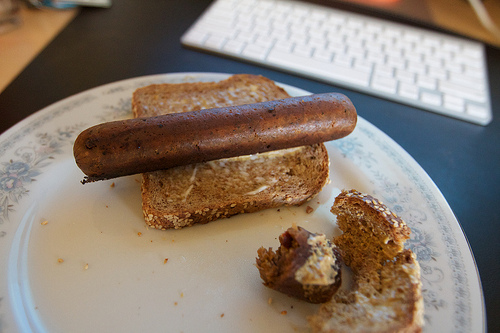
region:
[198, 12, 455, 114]
white blurred keyboard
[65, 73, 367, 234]
a hot dog on toast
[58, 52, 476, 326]
a hot dog on toast on a white plate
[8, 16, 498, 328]
a hot dog on toast on a white plate on a black mat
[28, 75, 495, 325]
a white plate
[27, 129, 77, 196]
floral design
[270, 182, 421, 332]
left overs on a plate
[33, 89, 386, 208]
a cooked frank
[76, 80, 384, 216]
a hot dog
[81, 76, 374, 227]
a hot dog on bread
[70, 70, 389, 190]
cooked sausage on brown bread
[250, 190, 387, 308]
mostly eaten sausage on eaten bread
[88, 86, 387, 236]
brown bread on white plate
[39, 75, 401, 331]
white plate on black table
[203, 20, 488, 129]
white wireless keyboard is above plate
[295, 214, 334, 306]
white spread on eaten sausage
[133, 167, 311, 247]
bread has white grains in crust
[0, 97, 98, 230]
blue floral pattern on plate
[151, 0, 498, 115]
keyboard is on black table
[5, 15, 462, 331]
black table has brown border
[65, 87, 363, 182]
Brown cooked hot dog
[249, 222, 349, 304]
Mostly eaten hot dog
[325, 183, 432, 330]
Mostly eaten piece of bread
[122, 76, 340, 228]
Piece of bread hot dog is sitting on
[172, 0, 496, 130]
White blurry key board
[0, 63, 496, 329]
white plate hot dogs are sitting on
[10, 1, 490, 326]
Brown table plate and keyboard are on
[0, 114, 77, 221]
Decorative pattern on white plate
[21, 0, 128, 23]
Blue blurry object in background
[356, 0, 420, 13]
Red blurry object in background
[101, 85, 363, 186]
the sausage is brown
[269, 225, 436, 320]
the bread has buttter on it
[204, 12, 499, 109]
the keyboard is white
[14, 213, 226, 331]
the plate is white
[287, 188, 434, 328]
the bread is hafly eaten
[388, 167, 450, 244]
markings are on the plate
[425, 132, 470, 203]
the surface is blue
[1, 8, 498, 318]
the scene is indoors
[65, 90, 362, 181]
the sausague is longer than bread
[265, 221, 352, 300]
butter is on the sausauge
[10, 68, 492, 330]
plate with sasauge on wheat bread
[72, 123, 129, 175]
tip end of sasauge sitting on wheat bread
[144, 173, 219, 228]
wheat bread with sasauge on it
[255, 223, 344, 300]
almost finished piece of sasauge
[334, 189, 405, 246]
tip of almost finished eaten wheat bread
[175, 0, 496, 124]
computer keyboardon table in front of plate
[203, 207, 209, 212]
seseme seed on wheat bread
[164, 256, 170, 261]
bread crumb on plate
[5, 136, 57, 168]
flowery decoration on plate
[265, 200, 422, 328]
one almost finished sausage sandwich